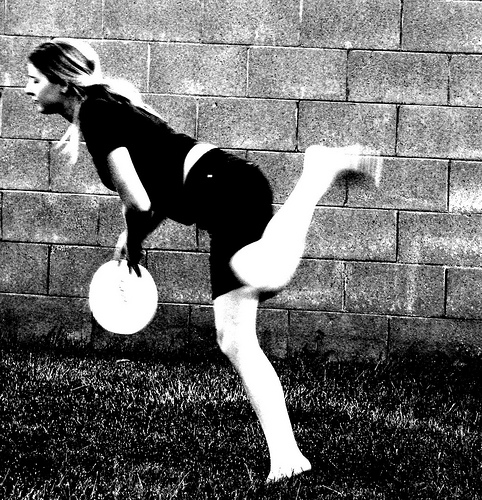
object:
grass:
[0, 350, 482, 499]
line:
[282, 385, 482, 446]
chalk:
[450, 187, 482, 212]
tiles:
[242, 44, 352, 103]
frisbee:
[87, 258, 160, 337]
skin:
[249, 365, 270, 403]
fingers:
[130, 258, 143, 279]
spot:
[203, 168, 215, 184]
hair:
[28, 37, 164, 164]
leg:
[209, 145, 385, 295]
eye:
[32, 78, 41, 85]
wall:
[0, 0, 482, 371]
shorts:
[181, 146, 275, 305]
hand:
[112, 229, 128, 261]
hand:
[125, 243, 144, 278]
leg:
[209, 241, 312, 483]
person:
[24, 35, 386, 487]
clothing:
[78, 90, 199, 227]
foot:
[302, 144, 384, 186]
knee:
[240, 253, 297, 294]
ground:
[0, 348, 482, 500]